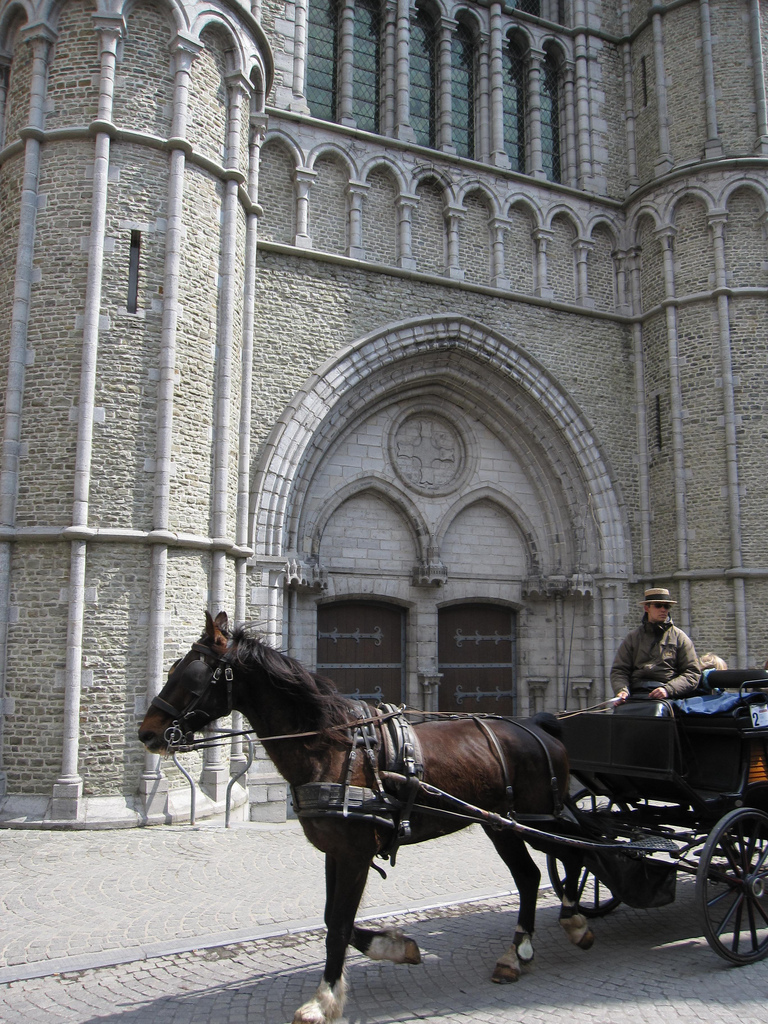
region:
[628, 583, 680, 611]
Man wearing a hat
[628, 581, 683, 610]
Man is wearing a hat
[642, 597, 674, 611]
Man wearing sunglasses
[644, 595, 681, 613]
Man is wearing sunglasses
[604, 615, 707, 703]
Man wearing a jacket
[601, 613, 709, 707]
Man is wearing a jacket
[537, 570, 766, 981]
Man sitting on a carriage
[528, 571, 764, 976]
Man is sitting on a carriage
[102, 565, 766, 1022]
Horse pulling a carriage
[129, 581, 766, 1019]
Horse is pulling a carriage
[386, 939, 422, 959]
hoof of the horse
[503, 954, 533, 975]
hoof of the horse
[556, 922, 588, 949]
hoof of the horse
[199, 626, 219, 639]
ear of the horse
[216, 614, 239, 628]
ear of the horse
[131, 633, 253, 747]
head of the horse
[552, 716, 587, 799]
tail of the horse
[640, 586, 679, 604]
hat on the man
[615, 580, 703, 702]
man on the horse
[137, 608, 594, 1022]
A brown horse carrying a carriage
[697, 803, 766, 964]
black wheel of a carriage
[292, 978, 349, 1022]
white hoof of a horse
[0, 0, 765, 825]
a cathedral made out of white bricks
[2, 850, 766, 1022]
a road with white bricks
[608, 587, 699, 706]
a man sitting in a carriage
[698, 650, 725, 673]
the blond head of a person sitting in a carriage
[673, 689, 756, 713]
a blue blanket sitting on a carriage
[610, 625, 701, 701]
a man wearing a brown winter coat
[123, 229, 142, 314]
A thin rectangular window.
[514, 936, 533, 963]
A white spot on the foot of the horse.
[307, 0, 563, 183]
Row of windows with steel railings.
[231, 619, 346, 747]
A long and black hair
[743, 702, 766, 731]
A white card with number on it.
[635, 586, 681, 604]
A brown hat with black line.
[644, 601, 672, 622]
Sunglasses on the mans' face.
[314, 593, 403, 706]
A brown wooded door.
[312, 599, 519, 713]
Doors with gray steel design.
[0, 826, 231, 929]
Gray bricks on the ground.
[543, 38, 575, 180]
A window on a building.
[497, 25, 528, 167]
A window on a building.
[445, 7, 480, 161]
A window on a building.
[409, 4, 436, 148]
A window on a building.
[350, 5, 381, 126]
A window on a building.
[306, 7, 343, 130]
A window on a building.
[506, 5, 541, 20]
A window on a building.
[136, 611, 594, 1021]
the horse is walking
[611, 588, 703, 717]
the man is sitting down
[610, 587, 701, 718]
the man is wearing a hat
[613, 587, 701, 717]
the man is wearing a jacket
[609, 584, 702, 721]
the man is wearing sunglasses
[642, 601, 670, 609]
the sunglasses are black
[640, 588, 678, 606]
the black ribbon on the hat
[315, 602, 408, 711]
the door is wide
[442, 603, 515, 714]
the door is brown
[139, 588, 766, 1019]
the man behind the horse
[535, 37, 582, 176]
A window on a building.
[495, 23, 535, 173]
A window on a building.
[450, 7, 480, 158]
A window on a building.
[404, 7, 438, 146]
A window on a building.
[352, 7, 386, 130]
A window on a building.